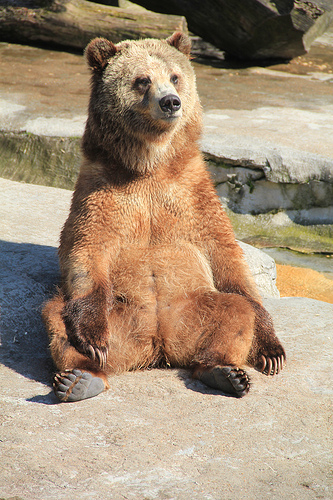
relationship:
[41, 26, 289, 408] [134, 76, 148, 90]
bear has eye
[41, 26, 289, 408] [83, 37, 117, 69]
bear has ear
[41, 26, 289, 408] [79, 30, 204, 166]
bear has head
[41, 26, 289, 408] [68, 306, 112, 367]
bear has paw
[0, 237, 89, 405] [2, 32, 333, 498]
shadow on ground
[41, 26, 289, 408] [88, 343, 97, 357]
bear has claws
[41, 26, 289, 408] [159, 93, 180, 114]
bear has nose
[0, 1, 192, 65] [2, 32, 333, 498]
log on ground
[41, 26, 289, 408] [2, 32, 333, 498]
bear on ground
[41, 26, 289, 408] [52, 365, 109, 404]
bear has foot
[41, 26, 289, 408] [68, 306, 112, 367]
bear has hand